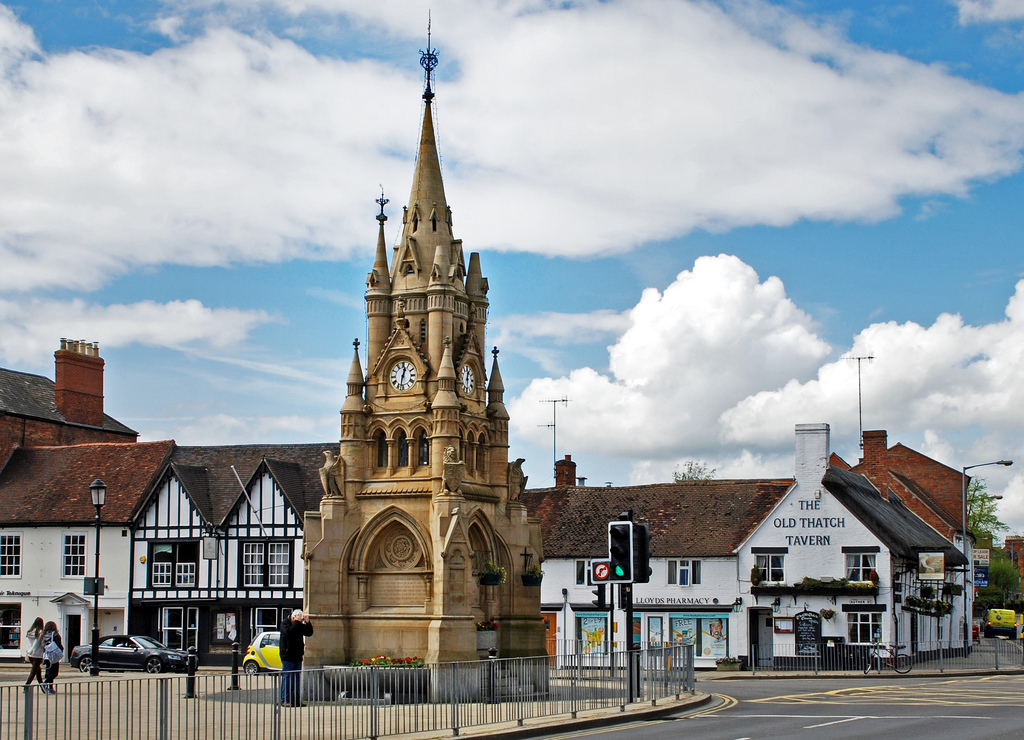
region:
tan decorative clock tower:
[303, 52, 551, 695]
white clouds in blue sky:
[501, 116, 584, 205]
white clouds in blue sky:
[468, 210, 590, 340]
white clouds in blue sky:
[637, 388, 707, 427]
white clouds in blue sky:
[727, 236, 833, 328]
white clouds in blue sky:
[767, 170, 876, 291]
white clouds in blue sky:
[49, 131, 158, 230]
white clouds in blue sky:
[185, 300, 244, 380]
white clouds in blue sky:
[111, 125, 206, 214]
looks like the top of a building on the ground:
[289, 10, 555, 701]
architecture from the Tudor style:
[0, 439, 333, 661]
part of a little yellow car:
[241, 629, 283, 672]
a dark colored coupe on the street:
[68, 631, 198, 677]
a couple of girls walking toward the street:
[23, 616, 59, 689]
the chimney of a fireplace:
[54, 339, 108, 412]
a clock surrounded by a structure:
[383, 351, 416, 399]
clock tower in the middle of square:
[296, 38, 546, 683]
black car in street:
[65, 630, 195, 675]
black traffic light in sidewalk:
[608, 515, 654, 700]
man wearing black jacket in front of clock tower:
[274, 601, 310, 704]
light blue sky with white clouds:
[4, 0, 1020, 482]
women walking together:
[21, 614, 66, 690]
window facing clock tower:
[59, 535, 86, 578]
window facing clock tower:
[0, 533, 23, 576]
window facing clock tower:
[0, 602, 24, 650]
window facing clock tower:
[150, 543, 175, 589]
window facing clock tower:
[176, 540, 198, 584]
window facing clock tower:
[240, 536, 269, 584]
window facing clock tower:
[264, 540, 289, 589]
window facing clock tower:
[752, 552, 769, 581]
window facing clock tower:
[766, 552, 786, 581]